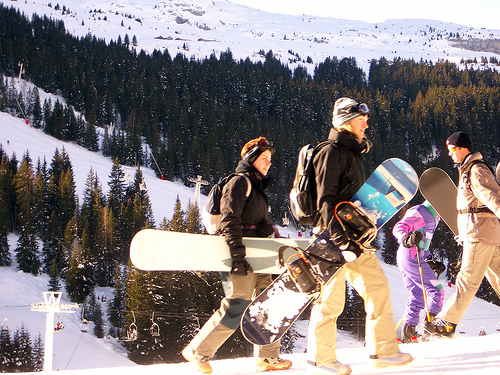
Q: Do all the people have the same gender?
A: No, they are both male and female.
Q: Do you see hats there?
A: Yes, there is a hat.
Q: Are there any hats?
A: Yes, there is a hat.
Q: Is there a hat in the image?
A: Yes, there is a hat.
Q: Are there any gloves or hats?
A: Yes, there is a hat.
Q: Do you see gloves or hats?
A: Yes, there is a hat.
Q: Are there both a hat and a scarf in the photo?
A: No, there is a hat but no scarves.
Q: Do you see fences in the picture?
A: No, there are no fences.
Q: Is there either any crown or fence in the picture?
A: No, there are no fences or crowns.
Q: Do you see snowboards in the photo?
A: Yes, there is a snowboard.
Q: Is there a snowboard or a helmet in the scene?
A: Yes, there is a snowboard.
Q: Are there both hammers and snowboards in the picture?
A: No, there is a snowboard but no hammers.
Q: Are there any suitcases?
A: No, there are no suitcases.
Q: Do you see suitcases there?
A: No, there are no suitcases.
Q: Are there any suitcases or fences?
A: No, there are no suitcases or fences.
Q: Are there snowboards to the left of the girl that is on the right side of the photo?
A: Yes, there is a snowboard to the left of the girl.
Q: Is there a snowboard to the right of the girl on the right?
A: No, the snowboard is to the left of the girl.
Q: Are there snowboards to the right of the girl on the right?
A: No, the snowboard is to the left of the girl.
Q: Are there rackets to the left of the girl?
A: No, there is a snowboard to the left of the girl.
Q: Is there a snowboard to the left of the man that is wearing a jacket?
A: Yes, there is a snowboard to the left of the man.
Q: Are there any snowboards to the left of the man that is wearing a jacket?
A: Yes, there is a snowboard to the left of the man.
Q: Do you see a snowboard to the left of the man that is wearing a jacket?
A: Yes, there is a snowboard to the left of the man.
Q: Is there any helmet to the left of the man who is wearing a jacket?
A: No, there is a snowboard to the left of the man.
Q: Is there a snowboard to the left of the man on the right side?
A: Yes, there is a snowboard to the left of the man.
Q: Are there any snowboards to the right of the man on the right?
A: No, the snowboard is to the left of the man.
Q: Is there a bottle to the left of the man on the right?
A: No, there is a snowboard to the left of the man.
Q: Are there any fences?
A: No, there are no fences.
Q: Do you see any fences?
A: No, there are no fences.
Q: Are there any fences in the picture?
A: No, there are no fences.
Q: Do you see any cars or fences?
A: No, there are no fences or cars.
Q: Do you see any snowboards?
A: Yes, there is a snowboard.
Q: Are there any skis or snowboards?
A: Yes, there is a snowboard.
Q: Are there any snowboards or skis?
A: Yes, there is a snowboard.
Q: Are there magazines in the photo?
A: No, there are no magazines.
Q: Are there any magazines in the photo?
A: No, there are no magazines.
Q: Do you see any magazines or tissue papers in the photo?
A: No, there are no magazines or tissue papers.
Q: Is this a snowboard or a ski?
A: This is a snowboard.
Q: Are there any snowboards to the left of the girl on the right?
A: Yes, there is a snowboard to the left of the girl.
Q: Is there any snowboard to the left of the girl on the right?
A: Yes, there is a snowboard to the left of the girl.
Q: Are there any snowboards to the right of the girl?
A: No, the snowboard is to the left of the girl.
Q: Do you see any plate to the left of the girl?
A: No, there is a snowboard to the left of the girl.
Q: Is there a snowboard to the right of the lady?
A: Yes, there is a snowboard to the right of the lady.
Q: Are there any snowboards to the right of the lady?
A: Yes, there is a snowboard to the right of the lady.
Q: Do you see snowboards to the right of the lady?
A: Yes, there is a snowboard to the right of the lady.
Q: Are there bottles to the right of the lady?
A: No, there is a snowboard to the right of the lady.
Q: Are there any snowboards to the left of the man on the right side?
A: Yes, there is a snowboard to the left of the man.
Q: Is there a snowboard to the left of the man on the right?
A: Yes, there is a snowboard to the left of the man.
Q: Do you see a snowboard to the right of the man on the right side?
A: No, the snowboard is to the left of the man.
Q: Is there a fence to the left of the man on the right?
A: No, there is a snowboard to the left of the man.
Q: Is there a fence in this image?
A: No, there are no fences.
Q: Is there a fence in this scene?
A: No, there are no fences.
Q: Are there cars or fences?
A: No, there are no fences or cars.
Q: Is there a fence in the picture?
A: No, there are no fences.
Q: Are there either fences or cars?
A: No, there are no fences or cars.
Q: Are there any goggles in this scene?
A: Yes, there are goggles.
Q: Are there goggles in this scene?
A: Yes, there are goggles.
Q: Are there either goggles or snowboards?
A: Yes, there are goggles.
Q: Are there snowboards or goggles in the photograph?
A: Yes, there are goggles.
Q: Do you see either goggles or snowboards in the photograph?
A: Yes, there are goggles.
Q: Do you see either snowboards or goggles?
A: Yes, there are goggles.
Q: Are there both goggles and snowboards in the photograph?
A: Yes, there are both goggles and a snowboard.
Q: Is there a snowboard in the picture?
A: Yes, there is a snowboard.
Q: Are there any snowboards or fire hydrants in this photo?
A: Yes, there is a snowboard.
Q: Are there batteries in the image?
A: No, there are no batteries.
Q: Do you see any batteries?
A: No, there are no batteries.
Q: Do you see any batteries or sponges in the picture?
A: No, there are no batteries or sponges.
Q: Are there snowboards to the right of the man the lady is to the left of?
A: Yes, there is a snowboard to the right of the man.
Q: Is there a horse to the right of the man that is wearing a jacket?
A: No, there is a snowboard to the right of the man.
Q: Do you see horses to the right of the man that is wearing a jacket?
A: No, there is a snowboard to the right of the man.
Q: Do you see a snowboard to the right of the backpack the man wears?
A: Yes, there is a snowboard to the right of the backpack.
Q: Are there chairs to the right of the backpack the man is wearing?
A: No, there is a snowboard to the right of the backpack.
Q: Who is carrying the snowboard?
A: The man is carrying the snowboard.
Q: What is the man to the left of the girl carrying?
A: The man is carrying a snowboard.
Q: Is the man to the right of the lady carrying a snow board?
A: Yes, the man is carrying a snow board.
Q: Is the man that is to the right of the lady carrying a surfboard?
A: No, the man is carrying a snow board.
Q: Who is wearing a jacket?
A: The man is wearing a jacket.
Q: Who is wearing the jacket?
A: The man is wearing a jacket.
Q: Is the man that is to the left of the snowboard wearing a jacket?
A: Yes, the man is wearing a jacket.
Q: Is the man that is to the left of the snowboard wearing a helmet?
A: No, the man is wearing a jacket.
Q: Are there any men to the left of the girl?
A: Yes, there is a man to the left of the girl.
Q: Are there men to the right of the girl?
A: No, the man is to the left of the girl.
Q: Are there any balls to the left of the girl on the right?
A: No, there is a man to the left of the girl.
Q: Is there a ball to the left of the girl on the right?
A: No, there is a man to the left of the girl.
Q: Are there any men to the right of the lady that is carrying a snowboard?
A: Yes, there is a man to the right of the lady.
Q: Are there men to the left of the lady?
A: No, the man is to the right of the lady.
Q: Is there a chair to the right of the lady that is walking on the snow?
A: No, there is a man to the right of the lady.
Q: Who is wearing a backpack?
A: The man is wearing a backpack.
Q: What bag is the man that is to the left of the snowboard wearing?
A: The man is wearing a backpack.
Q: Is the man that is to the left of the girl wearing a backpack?
A: Yes, the man is wearing a backpack.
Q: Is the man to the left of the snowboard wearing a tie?
A: No, the man is wearing a backpack.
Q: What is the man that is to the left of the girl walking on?
A: The man is walking on the snow.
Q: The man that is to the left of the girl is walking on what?
A: The man is walking on the snow.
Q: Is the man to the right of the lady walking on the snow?
A: Yes, the man is walking on the snow.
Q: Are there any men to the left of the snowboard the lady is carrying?
A: Yes, there is a man to the left of the snowboard.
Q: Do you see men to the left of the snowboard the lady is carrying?
A: Yes, there is a man to the left of the snowboard.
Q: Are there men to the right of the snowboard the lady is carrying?
A: No, the man is to the left of the snowboard.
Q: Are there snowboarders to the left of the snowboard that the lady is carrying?
A: No, there is a man to the left of the snowboard.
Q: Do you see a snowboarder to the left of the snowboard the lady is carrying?
A: No, there is a man to the left of the snowboard.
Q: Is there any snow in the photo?
A: Yes, there is snow.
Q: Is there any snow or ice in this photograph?
A: Yes, there is snow.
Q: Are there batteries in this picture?
A: No, there are no batteries.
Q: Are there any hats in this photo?
A: Yes, there is a hat.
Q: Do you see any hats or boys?
A: Yes, there is a hat.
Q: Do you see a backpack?
A: Yes, there is a backpack.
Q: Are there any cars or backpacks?
A: Yes, there is a backpack.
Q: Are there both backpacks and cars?
A: No, there is a backpack but no cars.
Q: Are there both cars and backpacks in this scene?
A: No, there is a backpack but no cars.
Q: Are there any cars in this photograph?
A: No, there are no cars.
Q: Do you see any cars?
A: No, there are no cars.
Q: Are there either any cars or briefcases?
A: No, there are no cars or briefcases.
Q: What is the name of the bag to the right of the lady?
A: The bag is a backpack.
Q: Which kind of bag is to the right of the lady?
A: The bag is a backpack.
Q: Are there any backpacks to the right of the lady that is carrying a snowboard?
A: Yes, there is a backpack to the right of the lady.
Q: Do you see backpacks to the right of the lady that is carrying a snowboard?
A: Yes, there is a backpack to the right of the lady.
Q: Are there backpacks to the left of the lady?
A: No, the backpack is to the right of the lady.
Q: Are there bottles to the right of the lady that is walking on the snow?
A: No, there is a backpack to the right of the lady.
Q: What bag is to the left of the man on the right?
A: The bag is a backpack.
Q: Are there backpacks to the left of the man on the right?
A: Yes, there is a backpack to the left of the man.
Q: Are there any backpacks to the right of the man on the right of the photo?
A: No, the backpack is to the left of the man.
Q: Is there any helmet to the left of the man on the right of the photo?
A: No, there is a backpack to the left of the man.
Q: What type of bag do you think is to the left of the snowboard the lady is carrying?
A: The bag is a backpack.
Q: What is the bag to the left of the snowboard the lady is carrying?
A: The bag is a backpack.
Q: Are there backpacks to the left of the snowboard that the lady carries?
A: Yes, there is a backpack to the left of the snowboard.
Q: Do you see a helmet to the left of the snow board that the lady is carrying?
A: No, there is a backpack to the left of the snowboard.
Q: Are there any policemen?
A: No, there are no policemen.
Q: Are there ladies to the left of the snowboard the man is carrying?
A: Yes, there is a lady to the left of the snowboard.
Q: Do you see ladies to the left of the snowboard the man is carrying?
A: Yes, there is a lady to the left of the snowboard.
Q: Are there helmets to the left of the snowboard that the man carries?
A: No, there is a lady to the left of the snowboard.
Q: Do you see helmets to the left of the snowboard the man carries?
A: No, there is a lady to the left of the snowboard.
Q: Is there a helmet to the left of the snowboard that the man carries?
A: No, there is a lady to the left of the snowboard.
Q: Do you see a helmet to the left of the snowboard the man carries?
A: No, there is a lady to the left of the snowboard.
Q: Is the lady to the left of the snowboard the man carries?
A: Yes, the lady is to the left of the snowboard.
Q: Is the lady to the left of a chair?
A: No, the lady is to the left of the snowboard.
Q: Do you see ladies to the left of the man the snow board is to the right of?
A: Yes, there is a lady to the left of the man.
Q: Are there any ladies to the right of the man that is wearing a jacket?
A: No, the lady is to the left of the man.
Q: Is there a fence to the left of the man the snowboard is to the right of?
A: No, there is a lady to the left of the man.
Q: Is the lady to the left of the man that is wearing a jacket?
A: Yes, the lady is to the left of the man.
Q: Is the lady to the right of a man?
A: No, the lady is to the left of a man.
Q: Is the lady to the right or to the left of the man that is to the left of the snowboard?
A: The lady is to the left of the man.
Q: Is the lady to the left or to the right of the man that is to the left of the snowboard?
A: The lady is to the left of the man.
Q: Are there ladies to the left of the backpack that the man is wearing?
A: Yes, there is a lady to the left of the backpack.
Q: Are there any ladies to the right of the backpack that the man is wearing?
A: No, the lady is to the left of the backpack.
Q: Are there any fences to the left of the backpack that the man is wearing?
A: No, there is a lady to the left of the backpack.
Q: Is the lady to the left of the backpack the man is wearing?
A: Yes, the lady is to the left of the backpack.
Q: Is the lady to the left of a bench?
A: No, the lady is to the left of the backpack.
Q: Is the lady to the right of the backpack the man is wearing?
A: No, the lady is to the left of the backpack.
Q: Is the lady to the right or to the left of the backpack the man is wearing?
A: The lady is to the left of the backpack.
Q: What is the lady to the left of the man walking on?
A: The lady is walking on the snow.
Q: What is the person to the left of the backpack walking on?
A: The lady is walking on the snow.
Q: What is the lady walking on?
A: The lady is walking on the snow.